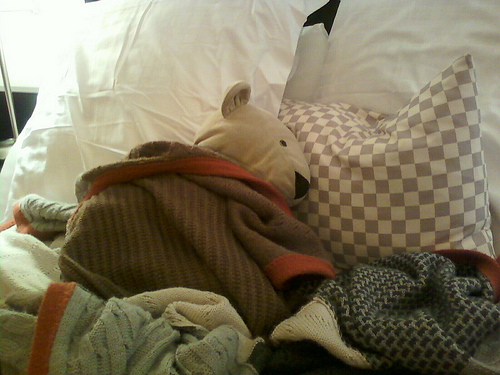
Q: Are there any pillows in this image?
A: Yes, there is a pillow.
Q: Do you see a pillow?
A: Yes, there is a pillow.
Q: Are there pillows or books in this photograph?
A: Yes, there is a pillow.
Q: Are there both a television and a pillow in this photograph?
A: No, there is a pillow but no televisions.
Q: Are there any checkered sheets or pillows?
A: Yes, there is a checkered pillow.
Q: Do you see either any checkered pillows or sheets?
A: Yes, there is a checkered pillow.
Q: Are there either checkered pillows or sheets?
A: Yes, there is a checkered pillow.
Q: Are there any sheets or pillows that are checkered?
A: Yes, the pillow is checkered.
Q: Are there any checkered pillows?
A: Yes, there is a checkered pillow.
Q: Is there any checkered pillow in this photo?
A: Yes, there is a checkered pillow.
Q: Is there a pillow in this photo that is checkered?
A: Yes, there is a pillow that is checkered.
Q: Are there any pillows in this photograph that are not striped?
A: Yes, there is a checkered pillow.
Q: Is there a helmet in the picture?
A: No, there are no helmets.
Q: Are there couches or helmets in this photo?
A: No, there are no helmets or couches.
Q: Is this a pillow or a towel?
A: This is a pillow.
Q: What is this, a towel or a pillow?
A: This is a pillow.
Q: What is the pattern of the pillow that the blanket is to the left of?
A: The pillow is checkered.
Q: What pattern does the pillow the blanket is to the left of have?
A: The pillow has checkered pattern.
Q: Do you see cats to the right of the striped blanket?
A: No, there is a pillow to the right of the blanket.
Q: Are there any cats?
A: No, there are no cats.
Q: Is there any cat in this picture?
A: No, there are no cats.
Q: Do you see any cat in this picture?
A: No, there are no cats.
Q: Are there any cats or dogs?
A: No, there are no cats or dogs.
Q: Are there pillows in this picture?
A: Yes, there is a pillow.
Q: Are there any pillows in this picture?
A: Yes, there is a pillow.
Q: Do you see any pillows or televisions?
A: Yes, there is a pillow.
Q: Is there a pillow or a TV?
A: Yes, there is a pillow.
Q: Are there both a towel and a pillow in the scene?
A: No, there is a pillow but no towels.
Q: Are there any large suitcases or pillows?
A: Yes, there is a large pillow.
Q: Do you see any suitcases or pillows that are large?
A: Yes, the pillow is large.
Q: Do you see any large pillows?
A: Yes, there is a large pillow.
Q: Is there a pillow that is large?
A: Yes, there is a pillow that is large.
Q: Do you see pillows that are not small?
A: Yes, there is a large pillow.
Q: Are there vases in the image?
A: No, there are no vases.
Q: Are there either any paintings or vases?
A: No, there are no vases or paintings.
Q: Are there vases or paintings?
A: No, there are no vases or paintings.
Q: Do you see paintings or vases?
A: No, there are no vases or paintings.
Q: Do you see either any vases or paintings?
A: No, there are no vases or paintings.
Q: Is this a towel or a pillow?
A: This is a pillow.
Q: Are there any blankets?
A: Yes, there is a blanket.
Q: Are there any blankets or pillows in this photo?
A: Yes, there is a blanket.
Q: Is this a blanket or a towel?
A: This is a blanket.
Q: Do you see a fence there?
A: No, there are no fences.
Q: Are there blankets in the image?
A: Yes, there is a blanket.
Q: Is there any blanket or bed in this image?
A: Yes, there is a blanket.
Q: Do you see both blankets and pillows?
A: Yes, there are both a blanket and a pillow.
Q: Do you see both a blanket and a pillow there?
A: Yes, there are both a blanket and a pillow.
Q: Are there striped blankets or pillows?
A: Yes, there is a striped blanket.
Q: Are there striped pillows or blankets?
A: Yes, there is a striped blanket.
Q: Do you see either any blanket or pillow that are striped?
A: Yes, the blanket is striped.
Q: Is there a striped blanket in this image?
A: Yes, there is a striped blanket.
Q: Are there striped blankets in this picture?
A: Yes, there is a striped blanket.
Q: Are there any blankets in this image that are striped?
A: Yes, there is a blanket that is striped.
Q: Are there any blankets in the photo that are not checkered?
A: Yes, there is a striped blanket.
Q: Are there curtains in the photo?
A: No, there are no curtains.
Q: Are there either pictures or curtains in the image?
A: No, there are no curtains or pictures.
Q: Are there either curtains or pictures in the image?
A: No, there are no curtains or pictures.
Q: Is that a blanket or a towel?
A: That is a blanket.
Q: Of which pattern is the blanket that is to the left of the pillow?
A: The blanket is striped.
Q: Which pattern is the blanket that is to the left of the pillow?
A: The blanket is striped.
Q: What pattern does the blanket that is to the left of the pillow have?
A: The blanket has striped pattern.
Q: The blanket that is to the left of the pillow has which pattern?
A: The blanket is striped.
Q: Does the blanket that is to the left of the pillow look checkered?
A: No, the blanket is striped.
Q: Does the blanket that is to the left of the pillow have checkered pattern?
A: No, the blanket is striped.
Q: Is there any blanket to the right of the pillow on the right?
A: No, the blanket is to the left of the pillow.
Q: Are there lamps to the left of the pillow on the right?
A: No, there is a blanket to the left of the pillow.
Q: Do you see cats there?
A: No, there are no cats.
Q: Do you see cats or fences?
A: No, there are no cats or fences.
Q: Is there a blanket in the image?
A: Yes, there is a blanket.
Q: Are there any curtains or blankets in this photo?
A: Yes, there is a blanket.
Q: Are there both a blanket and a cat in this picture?
A: No, there is a blanket but no cats.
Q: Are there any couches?
A: No, there are no couches.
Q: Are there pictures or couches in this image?
A: No, there are no couches or pictures.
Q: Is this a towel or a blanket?
A: This is a blanket.